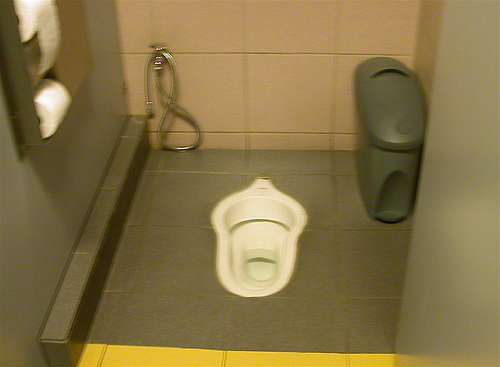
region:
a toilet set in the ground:
[210, 173, 308, 298]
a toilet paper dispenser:
[0, 1, 71, 148]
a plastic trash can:
[352, 56, 426, 223]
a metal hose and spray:
[143, 41, 200, 151]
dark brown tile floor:
[62, 148, 219, 346]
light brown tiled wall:
[196, 2, 357, 150]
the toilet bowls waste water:
[240, 247, 278, 287]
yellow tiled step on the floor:
[77, 351, 400, 366]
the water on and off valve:
[148, 38, 169, 53]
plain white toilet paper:
[31, 74, 70, 136]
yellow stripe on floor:
[86, 348, 401, 365]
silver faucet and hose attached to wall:
[131, 33, 208, 156]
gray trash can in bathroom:
[337, 49, 426, 234]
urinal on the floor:
[200, 167, 308, 304]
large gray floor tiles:
[128, 252, 208, 335]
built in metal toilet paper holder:
[10, 8, 111, 147]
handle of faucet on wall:
[142, 35, 172, 60]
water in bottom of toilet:
[235, 238, 282, 288]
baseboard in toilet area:
[71, 112, 149, 349]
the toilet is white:
[199, 153, 443, 360]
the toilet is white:
[153, 178, 284, 306]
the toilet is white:
[165, 89, 295, 284]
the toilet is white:
[170, 93, 350, 364]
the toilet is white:
[210, 121, 319, 341]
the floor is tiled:
[131, 246, 282, 353]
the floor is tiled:
[129, 278, 222, 357]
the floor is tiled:
[91, 236, 223, 358]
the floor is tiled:
[116, 238, 191, 338]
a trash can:
[350, 66, 422, 230]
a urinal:
[198, 189, 308, 306]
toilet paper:
[29, 83, 85, 130]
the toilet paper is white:
[23, 86, 95, 133]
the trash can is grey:
[356, 77, 418, 219]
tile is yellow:
[106, 342, 221, 365]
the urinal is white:
[225, 190, 291, 295]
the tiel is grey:
[146, 223, 186, 310]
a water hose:
[156, 61, 216, 154]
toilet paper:
[17, 8, 72, 45]